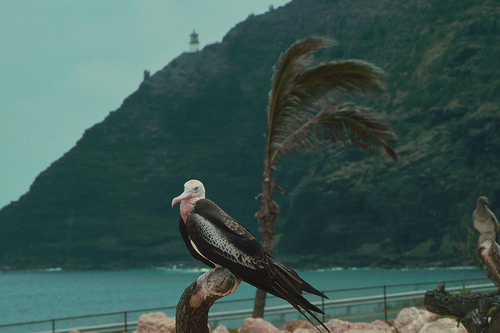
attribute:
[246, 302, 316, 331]
head — white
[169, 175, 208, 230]
head — white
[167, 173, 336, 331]
bird — black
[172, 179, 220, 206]
head — white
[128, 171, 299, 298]
bird — black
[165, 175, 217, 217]
head — white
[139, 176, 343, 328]
bird — black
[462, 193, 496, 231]
head — white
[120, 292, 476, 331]
rocks — pinkish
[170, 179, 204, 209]
head — white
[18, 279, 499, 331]
rail — metal, gray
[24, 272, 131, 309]
water — blue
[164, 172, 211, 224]
head — white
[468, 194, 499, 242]
bird — perched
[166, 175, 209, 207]
head — white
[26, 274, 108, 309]
water — blue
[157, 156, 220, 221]
head — white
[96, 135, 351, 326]
bird — black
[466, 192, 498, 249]
bird — black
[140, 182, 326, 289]
bird — black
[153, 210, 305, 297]
feathers — black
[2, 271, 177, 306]
water — blue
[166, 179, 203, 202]
head — white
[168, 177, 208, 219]
head — white